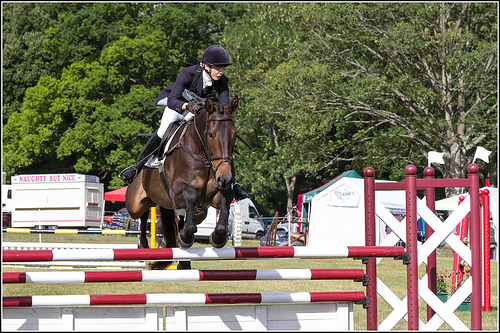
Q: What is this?
A: A riding stable setting.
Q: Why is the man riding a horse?
A: Practicing jumps.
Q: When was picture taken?
A: During daylight.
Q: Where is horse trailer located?
A: On left side.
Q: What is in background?
A: Trees.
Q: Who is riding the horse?
A: A man.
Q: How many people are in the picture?
A: One.